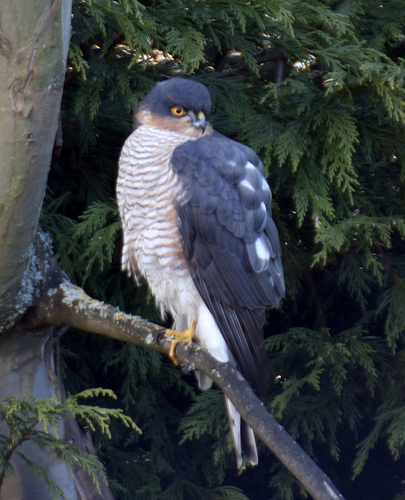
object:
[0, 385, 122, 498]
green branch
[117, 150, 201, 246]
breast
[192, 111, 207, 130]
beak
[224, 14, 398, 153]
tree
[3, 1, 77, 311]
bark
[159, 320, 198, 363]
foot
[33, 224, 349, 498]
branch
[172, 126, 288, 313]
wing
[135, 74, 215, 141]
head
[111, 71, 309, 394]
bird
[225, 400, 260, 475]
tail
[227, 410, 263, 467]
feather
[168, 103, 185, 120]
eye